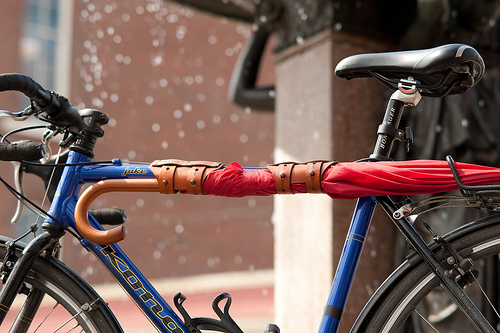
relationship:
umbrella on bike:
[73, 159, 497, 244] [3, 40, 483, 331]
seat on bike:
[332, 43, 484, 96] [3, 40, 483, 331]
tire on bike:
[0, 233, 126, 332] [3, 40, 483, 331]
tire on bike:
[348, 212, 500, 332] [3, 40, 483, 331]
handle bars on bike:
[0, 72, 109, 224] [3, 40, 483, 331]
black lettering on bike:
[100, 246, 190, 333] [3, 40, 483, 331]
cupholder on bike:
[174, 289, 282, 331] [3, 40, 483, 331]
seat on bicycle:
[332, 43, 484, 96] [1, 35, 497, 330]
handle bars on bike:
[0, 62, 122, 226] [3, 40, 483, 331]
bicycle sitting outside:
[0, 43, 499, 331] [2, 2, 498, 329]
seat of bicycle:
[332, 48, 486, 93] [0, 43, 499, 331]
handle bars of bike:
[0, 72, 109, 224] [3, 40, 483, 331]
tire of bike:
[337, 212, 498, 325] [3, 40, 483, 331]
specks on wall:
[59, 10, 267, 262] [2, 2, 281, 289]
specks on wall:
[80, 1, 190, 47] [6, 48, 266, 283]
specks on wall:
[80, 1, 190, 47] [133, 48, 212, 143]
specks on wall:
[80, 1, 231, 160] [92, 7, 262, 147]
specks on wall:
[152, 54, 198, 86] [59, 18, 265, 168]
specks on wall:
[139, 199, 189, 233] [111, 193, 276, 273]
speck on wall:
[141, 88, 160, 112] [2, 2, 281, 289]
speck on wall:
[169, 102, 185, 123] [2, 2, 281, 289]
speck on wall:
[124, 143, 142, 167] [2, 2, 281, 289]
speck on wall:
[226, 110, 245, 131] [2, 2, 281, 289]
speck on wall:
[147, 49, 172, 75] [2, 2, 281, 289]